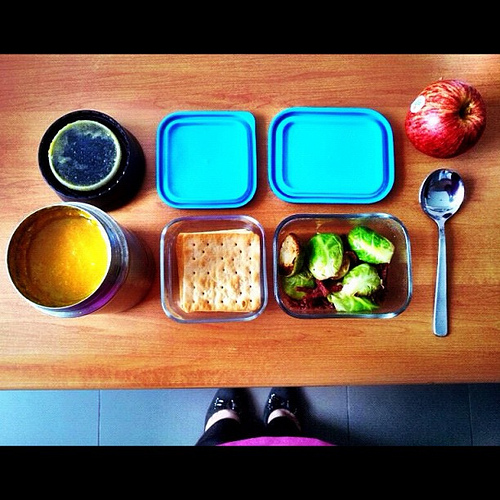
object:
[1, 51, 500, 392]
table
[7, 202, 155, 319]
cup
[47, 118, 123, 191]
lid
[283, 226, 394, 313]
vegetables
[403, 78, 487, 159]
apple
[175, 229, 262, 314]
bread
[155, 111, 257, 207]
lid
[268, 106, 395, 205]
lid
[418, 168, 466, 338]
spoon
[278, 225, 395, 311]
salad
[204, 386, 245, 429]
shoe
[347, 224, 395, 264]
lettuce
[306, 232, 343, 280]
lettuce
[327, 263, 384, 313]
lettuce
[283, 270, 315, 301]
lettuce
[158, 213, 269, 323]
bowl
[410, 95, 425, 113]
sticker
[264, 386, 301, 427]
shoe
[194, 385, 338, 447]
female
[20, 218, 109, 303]
soup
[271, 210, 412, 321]
bowl